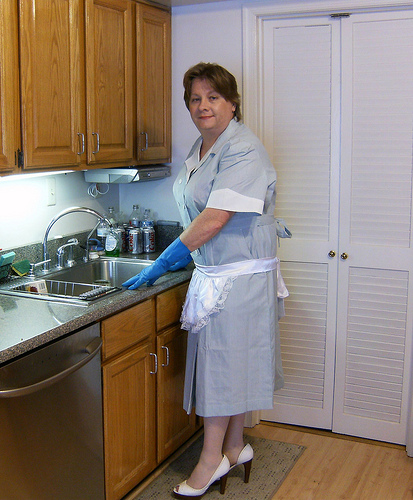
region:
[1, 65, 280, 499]
maid washing dishes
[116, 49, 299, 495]
woman wearing rubber gloves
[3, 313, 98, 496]
grey undercounter dishwasher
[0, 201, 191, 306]
silver counter-top kitchen sink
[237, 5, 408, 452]
wooden pantry doors painted white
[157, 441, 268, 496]
white high heels with brown stiletto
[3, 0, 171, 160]
brown wooden cabinets with handles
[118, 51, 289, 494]
woman in maid uniform smiling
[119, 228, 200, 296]
blue rubber gloves on hands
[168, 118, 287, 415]
blue lacy maid uniform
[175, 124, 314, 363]
woman wearing a blue maid uniform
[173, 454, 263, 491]
a woman wearing white peeptoe shoes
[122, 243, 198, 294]
a woman wearing blue latex gloves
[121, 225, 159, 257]
coke cans sitting on a counter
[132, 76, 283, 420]
A maid standing at a sink.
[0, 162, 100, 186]
a light shining over a sink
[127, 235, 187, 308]
a maid wearing blue latex gloves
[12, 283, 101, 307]
a drain sitting in a sink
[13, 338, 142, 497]
dishwasher installed inside a cabinet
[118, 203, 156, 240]
bottles sitting behind the coke cans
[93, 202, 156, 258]
Empty drink bottles and cans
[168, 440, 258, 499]
White open toe high heals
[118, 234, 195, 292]
Blue rubber cleaning gloves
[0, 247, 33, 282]
Two cleaning sponges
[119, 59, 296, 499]
Woman in blue maid outfit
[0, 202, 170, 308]
Stainless steel kitchen sink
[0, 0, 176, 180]
Wooden kitchen cupboards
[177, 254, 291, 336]
White laced apron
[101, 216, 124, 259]
Green dish washing detergent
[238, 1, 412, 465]
White closet door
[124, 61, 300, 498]
woman standing in the kitchen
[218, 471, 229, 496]
tall heel on the shoe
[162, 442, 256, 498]
brown and white heels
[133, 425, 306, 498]
small mat on the floor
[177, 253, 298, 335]
apron around the waist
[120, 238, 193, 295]
blue gloves on the hands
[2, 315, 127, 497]
dishwasher under the counter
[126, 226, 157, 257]
two silver coke cans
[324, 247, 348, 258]
two small gold knobs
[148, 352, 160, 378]
silver handle on the cabinet door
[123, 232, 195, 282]
woman with blue gloves on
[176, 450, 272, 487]
brown and white high heels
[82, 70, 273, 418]
lady standing at the sink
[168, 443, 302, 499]
feet on a floor mat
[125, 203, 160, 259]
cans and bottles in the corner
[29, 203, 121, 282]
faucets are made of chrome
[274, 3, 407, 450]
doors to a closet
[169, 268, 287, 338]
apron on the lady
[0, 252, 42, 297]
sponge by the faucet